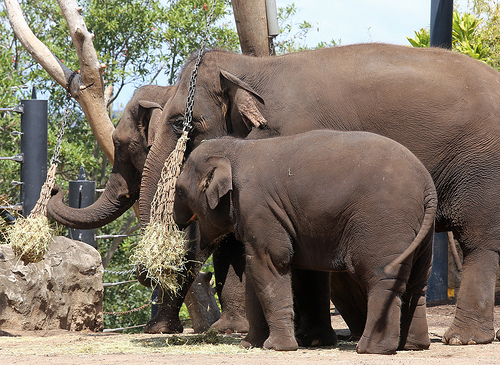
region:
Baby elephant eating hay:
[120, 130, 435, 355]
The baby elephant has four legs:
[252, 307, 429, 363]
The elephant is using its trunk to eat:
[27, 160, 133, 227]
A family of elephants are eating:
[52, 42, 498, 352]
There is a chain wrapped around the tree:
[50, 60, 88, 90]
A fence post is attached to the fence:
[6, 79, 52, 228]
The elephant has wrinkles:
[413, 70, 493, 225]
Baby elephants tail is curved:
[361, 153, 461, 289]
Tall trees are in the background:
[91, 7, 223, 74]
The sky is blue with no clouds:
[315, 5, 395, 43]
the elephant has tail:
[231, 161, 498, 290]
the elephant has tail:
[176, 136, 496, 360]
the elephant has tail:
[207, 157, 390, 348]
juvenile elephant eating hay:
[170, 138, 445, 363]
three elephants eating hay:
[1, 48, 496, 358]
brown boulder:
[2, 228, 107, 347]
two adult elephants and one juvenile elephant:
[64, 41, 496, 358]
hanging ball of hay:
[3, 105, 63, 277]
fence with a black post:
[2, 96, 49, 217]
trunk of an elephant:
[44, 180, 136, 235]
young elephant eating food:
[161, 129, 463, 362]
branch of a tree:
[3, 1, 115, 152]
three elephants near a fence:
[23, 36, 498, 358]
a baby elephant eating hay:
[132, 129, 440, 352]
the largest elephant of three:
[141, 44, 499, 345]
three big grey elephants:
[47, 41, 499, 353]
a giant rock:
[1, 236, 105, 335]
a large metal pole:
[21, 98, 48, 218]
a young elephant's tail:
[382, 183, 438, 273]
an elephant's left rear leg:
[444, 249, 498, 344]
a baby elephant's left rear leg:
[359, 285, 400, 352]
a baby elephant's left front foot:
[261, 328, 301, 353]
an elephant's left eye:
[169, 119, 200, 134]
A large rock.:
[0, 231, 110, 341]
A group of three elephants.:
[91, 37, 486, 354]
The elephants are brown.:
[96, 43, 496, 362]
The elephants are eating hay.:
[118, 211, 194, 311]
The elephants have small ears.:
[184, 147, 247, 221]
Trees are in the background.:
[3, 0, 186, 75]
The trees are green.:
[83, 2, 202, 54]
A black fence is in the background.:
[1, 97, 96, 254]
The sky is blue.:
[300, 1, 410, 38]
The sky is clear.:
[322, 0, 417, 22]